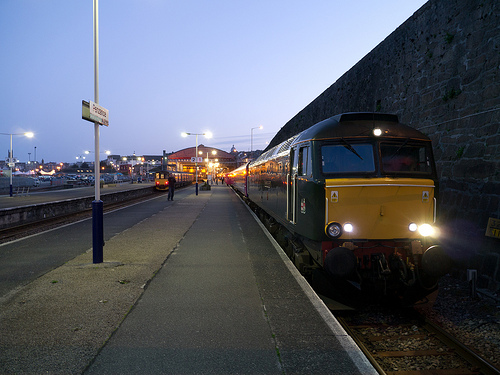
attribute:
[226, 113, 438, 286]
train — yellow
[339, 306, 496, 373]
tracks — steel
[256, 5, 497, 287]
wall — rock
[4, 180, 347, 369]
sidewalk — gray